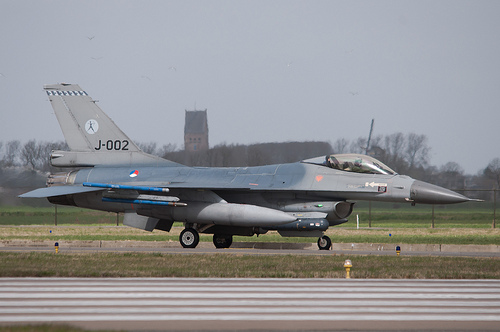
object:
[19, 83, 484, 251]
airplane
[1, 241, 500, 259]
tarmac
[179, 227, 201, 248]
tire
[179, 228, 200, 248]
wheel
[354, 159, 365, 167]
pilot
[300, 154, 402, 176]
cockpit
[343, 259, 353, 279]
marking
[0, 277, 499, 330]
runway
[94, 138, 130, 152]
numbers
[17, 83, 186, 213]
tail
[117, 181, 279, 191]
wing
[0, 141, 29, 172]
trees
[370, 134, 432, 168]
trees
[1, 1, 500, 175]
sky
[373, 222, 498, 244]
grass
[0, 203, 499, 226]
fence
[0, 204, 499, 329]
airport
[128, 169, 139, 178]
decal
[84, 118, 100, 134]
decal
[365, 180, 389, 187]
arrow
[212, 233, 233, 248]
wheel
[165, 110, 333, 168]
building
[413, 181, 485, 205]
nose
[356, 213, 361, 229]
pole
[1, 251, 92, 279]
grass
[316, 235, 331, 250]
front wheel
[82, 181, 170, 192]
rod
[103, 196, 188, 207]
rod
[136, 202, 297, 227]
cylinder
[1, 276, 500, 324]
lines